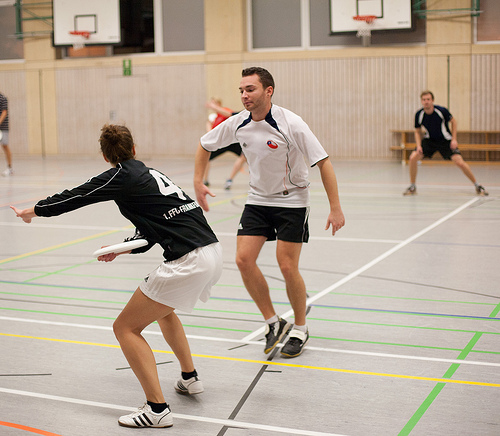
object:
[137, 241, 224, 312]
shorts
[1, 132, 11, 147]
shorts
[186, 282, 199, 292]
white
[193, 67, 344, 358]
man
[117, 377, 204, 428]
sneakers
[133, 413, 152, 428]
stripes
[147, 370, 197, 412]
socks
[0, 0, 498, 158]
wall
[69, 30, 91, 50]
hoop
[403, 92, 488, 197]
man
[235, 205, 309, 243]
shorts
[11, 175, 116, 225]
arm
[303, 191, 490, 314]
lines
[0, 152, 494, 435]
court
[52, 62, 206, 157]
door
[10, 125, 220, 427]
man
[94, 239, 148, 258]
frisbee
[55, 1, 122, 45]
backboard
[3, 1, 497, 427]
gym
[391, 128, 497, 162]
benches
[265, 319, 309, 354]
shoes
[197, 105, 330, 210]
shirt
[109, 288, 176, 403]
leg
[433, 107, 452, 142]
stripe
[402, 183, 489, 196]
shoes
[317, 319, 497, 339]
lines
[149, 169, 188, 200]
number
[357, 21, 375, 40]
net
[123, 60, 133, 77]
sign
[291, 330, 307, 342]
stripes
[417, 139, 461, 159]
shorts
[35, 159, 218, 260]
jacket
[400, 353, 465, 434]
stripe